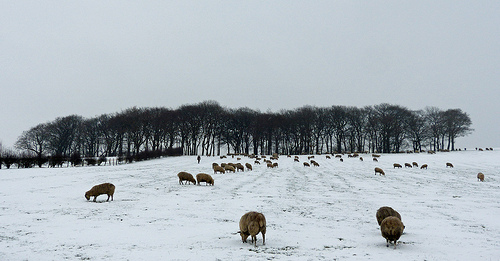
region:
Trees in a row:
[21, 104, 486, 151]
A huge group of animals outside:
[84, 148, 499, 248]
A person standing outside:
[192, 155, 204, 164]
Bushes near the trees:
[3, 150, 179, 164]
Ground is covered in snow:
[10, 155, 455, 259]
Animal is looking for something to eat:
[233, 208, 267, 239]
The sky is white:
[12, 5, 499, 141]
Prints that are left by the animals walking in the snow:
[5, 151, 490, 255]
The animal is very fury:
[233, 213, 272, 251]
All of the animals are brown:
[84, 152, 491, 251]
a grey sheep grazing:
[235, 206, 265, 243]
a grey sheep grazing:
[378, 213, 403, 244]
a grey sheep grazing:
[375, 203, 403, 228]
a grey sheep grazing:
[83, 178, 115, 202]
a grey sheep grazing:
[177, 166, 197, 185]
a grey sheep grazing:
[193, 168, 210, 184]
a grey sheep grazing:
[371, 162, 384, 174]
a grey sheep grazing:
[476, 168, 483, 178]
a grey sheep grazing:
[393, 159, 402, 168]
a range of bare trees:
[16, 100, 473, 159]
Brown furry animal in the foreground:
[228, 206, 273, 246]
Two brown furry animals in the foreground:
[367, 198, 415, 252]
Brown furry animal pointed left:
[74, 169, 126, 210]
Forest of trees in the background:
[18, 100, 484, 163]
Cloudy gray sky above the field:
[1, 1, 498, 102]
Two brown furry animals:
[174, 164, 222, 196]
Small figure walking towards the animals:
[192, 150, 203, 165]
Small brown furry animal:
[473, 164, 489, 184]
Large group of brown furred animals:
[210, 154, 257, 177]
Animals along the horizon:
[411, 141, 498, 156]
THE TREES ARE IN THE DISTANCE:
[14, 97, 488, 160]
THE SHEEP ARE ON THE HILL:
[78, 146, 497, 246]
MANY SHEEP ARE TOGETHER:
[78, 143, 498, 258]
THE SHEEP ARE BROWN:
[78, 144, 495, 244]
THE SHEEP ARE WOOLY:
[78, 150, 497, 260]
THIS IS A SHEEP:
[76, 175, 123, 210]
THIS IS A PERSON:
[192, 150, 204, 163]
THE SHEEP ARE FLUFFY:
[75, 153, 497, 259]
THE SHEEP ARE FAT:
[78, 149, 498, 246]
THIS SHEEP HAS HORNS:
[233, 210, 282, 255]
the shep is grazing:
[232, 201, 292, 249]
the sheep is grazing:
[77, 183, 126, 212]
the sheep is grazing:
[368, 163, 398, 183]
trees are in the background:
[99, 115, 462, 155]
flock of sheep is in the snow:
[191, 137, 473, 242]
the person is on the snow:
[185, 149, 210, 172]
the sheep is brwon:
[226, 206, 279, 258]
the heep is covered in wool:
[358, 200, 410, 241]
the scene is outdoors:
[6, 12, 498, 257]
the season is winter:
[1, 3, 488, 255]